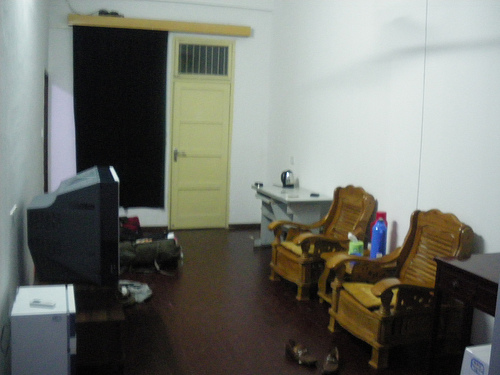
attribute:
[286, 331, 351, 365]
shoes — brown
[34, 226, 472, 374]
floor — wooden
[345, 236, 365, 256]
tissues — green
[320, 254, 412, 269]
table — brown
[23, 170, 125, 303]
tv — black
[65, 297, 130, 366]
stand — wooden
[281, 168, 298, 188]
coffee pot — silver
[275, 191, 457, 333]
chairs — wooden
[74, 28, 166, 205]
curtains — black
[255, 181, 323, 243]
desk — gray, grey, white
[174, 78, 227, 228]
door — striped, yellow, light yellow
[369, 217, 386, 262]
bottle — blue, large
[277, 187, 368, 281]
chair — wooden, brown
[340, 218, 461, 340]
chair — brown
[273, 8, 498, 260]
wall — white